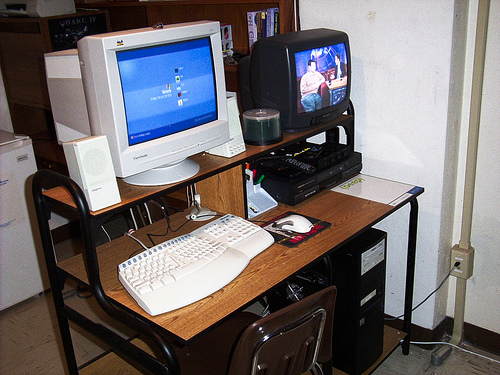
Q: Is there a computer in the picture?
A: Yes, there is a computer.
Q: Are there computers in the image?
A: Yes, there is a computer.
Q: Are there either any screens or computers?
A: Yes, there is a computer.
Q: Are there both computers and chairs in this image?
A: Yes, there are both a computer and a chair.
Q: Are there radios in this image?
A: No, there are no radios.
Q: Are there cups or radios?
A: No, there are no radios or cups.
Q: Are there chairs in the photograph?
A: Yes, there is a chair.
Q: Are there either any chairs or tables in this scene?
A: Yes, there is a chair.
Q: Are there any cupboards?
A: No, there are no cupboards.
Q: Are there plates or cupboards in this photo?
A: No, there are no cupboards or plates.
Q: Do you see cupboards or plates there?
A: No, there are no cupboards or plates.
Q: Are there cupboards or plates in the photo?
A: No, there are no cupboards or plates.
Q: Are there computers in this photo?
A: Yes, there is a computer.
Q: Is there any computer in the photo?
A: Yes, there is a computer.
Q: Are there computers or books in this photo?
A: Yes, there is a computer.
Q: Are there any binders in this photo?
A: No, there are no binders.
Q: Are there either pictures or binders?
A: No, there are no binders or pictures.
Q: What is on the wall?
A: The electric outlet is on the wall.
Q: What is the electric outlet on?
A: The electric outlet is on the wall.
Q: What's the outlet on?
A: The electric outlet is on the wall.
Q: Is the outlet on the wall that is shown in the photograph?
A: Yes, the outlet is on the wall.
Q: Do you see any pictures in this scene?
A: No, there are no pictures.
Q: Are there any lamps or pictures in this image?
A: No, there are no pictures or lamps.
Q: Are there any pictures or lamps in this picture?
A: No, there are no pictures or lamps.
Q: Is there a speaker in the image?
A: Yes, there is a speaker.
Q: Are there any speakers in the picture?
A: Yes, there is a speaker.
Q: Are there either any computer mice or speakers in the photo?
A: Yes, there is a speaker.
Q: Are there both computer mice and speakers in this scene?
A: Yes, there are both a speaker and a computer mouse.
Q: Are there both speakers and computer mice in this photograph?
A: Yes, there are both a speaker and a computer mouse.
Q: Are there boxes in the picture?
A: No, there are no boxes.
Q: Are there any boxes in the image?
A: No, there are no boxes.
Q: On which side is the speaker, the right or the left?
A: The speaker is on the left of the image.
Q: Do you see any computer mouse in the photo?
A: Yes, there is a computer mouse.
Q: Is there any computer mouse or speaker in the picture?
A: Yes, there is a computer mouse.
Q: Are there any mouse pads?
A: Yes, there is a mouse pad.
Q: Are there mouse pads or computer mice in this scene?
A: Yes, there is a mouse pad.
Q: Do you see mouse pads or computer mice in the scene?
A: Yes, there is a mouse pad.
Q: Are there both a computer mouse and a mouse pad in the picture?
A: Yes, there are both a mouse pad and a computer mouse.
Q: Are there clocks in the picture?
A: No, there are no clocks.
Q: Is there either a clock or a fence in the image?
A: No, there are no clocks or fences.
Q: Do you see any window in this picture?
A: Yes, there are windows.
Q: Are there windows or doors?
A: Yes, there are windows.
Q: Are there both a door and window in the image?
A: No, there are windows but no doors.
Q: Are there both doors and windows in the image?
A: No, there are windows but no doors.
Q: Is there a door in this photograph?
A: No, there are no doors.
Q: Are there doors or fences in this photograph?
A: No, there are no doors or fences.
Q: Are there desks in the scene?
A: Yes, there is a desk.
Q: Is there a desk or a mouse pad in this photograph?
A: Yes, there is a desk.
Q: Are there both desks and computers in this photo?
A: Yes, there are both a desk and a computer.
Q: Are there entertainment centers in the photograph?
A: No, there are no entertainment centers.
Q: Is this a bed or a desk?
A: This is a desk.